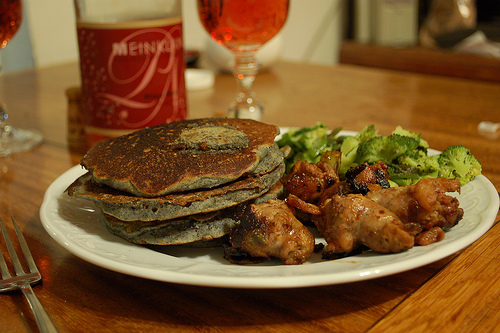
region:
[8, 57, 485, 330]
the wooden table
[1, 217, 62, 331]
a silver fork on the table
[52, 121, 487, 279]
a white plate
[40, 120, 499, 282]
food on the plate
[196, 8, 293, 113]
a wine glass on the table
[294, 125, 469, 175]
broccoli on the plate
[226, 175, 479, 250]
meat on the plate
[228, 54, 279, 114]
the base of the wine glass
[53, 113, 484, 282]
a dinner plate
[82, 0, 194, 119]
a bottle on the table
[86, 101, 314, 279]
a stack of pancakes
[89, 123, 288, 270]
a stack of pancakes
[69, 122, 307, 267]
a stack of pancakes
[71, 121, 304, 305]
a stack of pancakes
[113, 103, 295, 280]
a stack of pancakes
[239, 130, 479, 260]
the meat on the plate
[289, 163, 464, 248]
the meat on the plate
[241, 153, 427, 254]
the meat on the plate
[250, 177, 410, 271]
the meat on the plate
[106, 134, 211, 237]
pancakes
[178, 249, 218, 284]
a white plate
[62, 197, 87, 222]
a shadow on the plate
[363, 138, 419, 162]
brocolli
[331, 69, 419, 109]
the table is brown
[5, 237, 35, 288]
a fork on the table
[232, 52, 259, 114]
handle of a glass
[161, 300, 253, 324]
a shadow on the table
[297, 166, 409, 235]
chicken on the plate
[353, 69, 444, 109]
the table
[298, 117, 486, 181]
fresh cooked green broccoli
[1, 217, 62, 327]
silver clean fork on the table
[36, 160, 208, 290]
white dinner glass plate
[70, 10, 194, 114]
a bottle of red wine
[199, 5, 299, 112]
a glass of red wine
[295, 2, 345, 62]
white clean kitchen wall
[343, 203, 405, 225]
red seasoning on the chicken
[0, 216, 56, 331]
A silver fork on a table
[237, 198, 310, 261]
A piece of meat on a plate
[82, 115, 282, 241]
Pancakes on a white plate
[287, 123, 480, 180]
Green vegetables on a plate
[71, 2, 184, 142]
A glass bottle near a plate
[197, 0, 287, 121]
A wine glass near a plate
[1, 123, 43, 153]
The glass base of a wine glass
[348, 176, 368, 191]
A burned piece of meat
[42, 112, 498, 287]
A white plate filled with food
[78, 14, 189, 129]
A red label on a bottle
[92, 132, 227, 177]
food on a plate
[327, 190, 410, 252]
food on a plate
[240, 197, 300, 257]
food on a plate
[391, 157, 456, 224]
food on a plate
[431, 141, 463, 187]
brocoli on a plate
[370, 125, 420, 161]
brocoli on a plate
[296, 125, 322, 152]
brocoli on a plate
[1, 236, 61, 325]
fork on a table